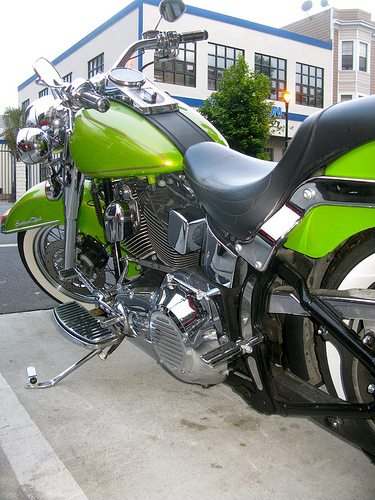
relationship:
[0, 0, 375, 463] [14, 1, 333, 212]
motorcycle in front of building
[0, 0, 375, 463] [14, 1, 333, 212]
motorcycle parked in front off building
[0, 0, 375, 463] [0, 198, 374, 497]
motorcycle in parking lot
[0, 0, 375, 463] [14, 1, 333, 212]
motorcycle parked next to building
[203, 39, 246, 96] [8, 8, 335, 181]
windows on building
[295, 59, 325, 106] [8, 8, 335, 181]
windows on building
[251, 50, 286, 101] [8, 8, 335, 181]
windows on building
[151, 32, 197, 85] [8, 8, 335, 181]
windows on building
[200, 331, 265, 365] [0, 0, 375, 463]
foot holder on motorcycle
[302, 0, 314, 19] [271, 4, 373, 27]
satellite on roof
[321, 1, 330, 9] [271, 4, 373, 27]
satellite on roof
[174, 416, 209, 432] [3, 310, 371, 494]
grease on pavement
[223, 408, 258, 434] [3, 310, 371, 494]
grease on pavement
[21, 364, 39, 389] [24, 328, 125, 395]
bolt on kickstand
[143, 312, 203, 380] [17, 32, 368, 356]
grate on motorcycle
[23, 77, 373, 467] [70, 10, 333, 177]
motorcycle front of building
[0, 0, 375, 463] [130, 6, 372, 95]
motorcycle front of building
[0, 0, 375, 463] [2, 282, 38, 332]
motorcycle in parking lot